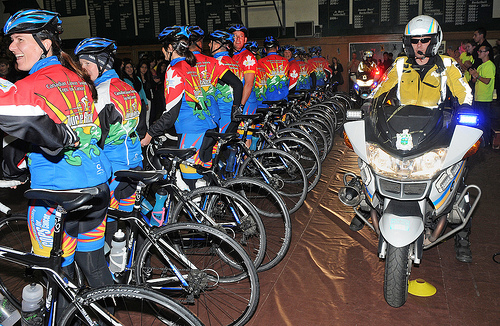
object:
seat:
[108, 168, 167, 187]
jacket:
[367, 53, 473, 109]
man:
[344, 14, 479, 266]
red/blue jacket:
[1, 58, 110, 192]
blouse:
[0, 55, 116, 192]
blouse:
[92, 68, 143, 164]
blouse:
[146, 57, 216, 137]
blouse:
[191, 48, 228, 128]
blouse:
[217, 53, 243, 80]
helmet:
[4, 8, 60, 34]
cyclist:
[0, 8, 104, 317]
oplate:
[408, 278, 437, 297]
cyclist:
[141, 24, 227, 188]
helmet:
[157, 25, 193, 41]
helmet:
[399, 14, 444, 58]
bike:
[338, 98, 486, 307]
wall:
[114, 0, 499, 90]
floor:
[269, 223, 381, 326]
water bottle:
[108, 228, 127, 274]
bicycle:
[0, 171, 259, 325]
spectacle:
[408, 36, 431, 45]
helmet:
[74, 35, 118, 56]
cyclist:
[72, 36, 149, 284]